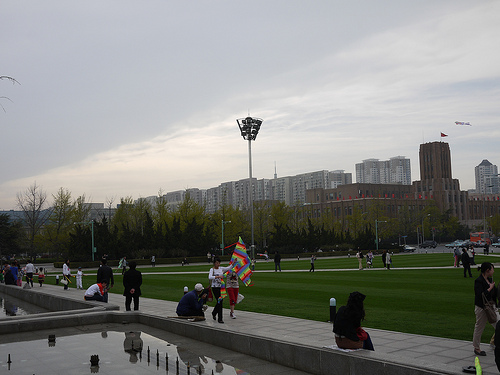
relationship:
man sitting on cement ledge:
[174, 281, 211, 321] [149, 298, 331, 364]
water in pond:
[1, 299, 24, 317] [0, 282, 294, 372]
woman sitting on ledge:
[329, 289, 376, 354] [200, 320, 280, 347]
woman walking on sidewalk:
[467, 257, 499, 355] [15, 267, 497, 374]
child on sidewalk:
[74, 267, 83, 287] [0, 279, 497, 374]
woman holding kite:
[209, 251, 239, 318] [228, 238, 257, 285]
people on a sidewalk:
[5, 252, 144, 310] [54, 270, 494, 373]